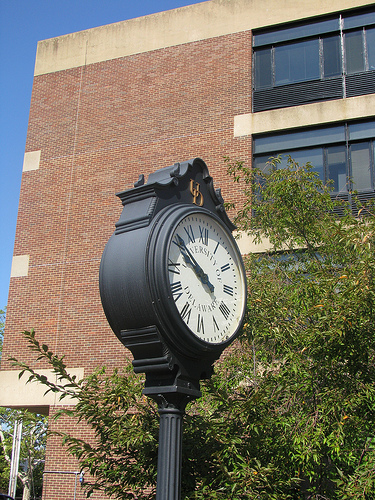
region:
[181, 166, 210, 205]
UD on the clock.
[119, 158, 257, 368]
The frame is black.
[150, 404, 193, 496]
The pole is black.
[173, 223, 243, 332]
The numbers are Roman Numerals.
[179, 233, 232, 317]
University of Delaware on the clock.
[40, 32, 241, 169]
The building is brick.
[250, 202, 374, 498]
The leaves are green.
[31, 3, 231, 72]
Tan on the building.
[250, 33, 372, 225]
Windows on the building.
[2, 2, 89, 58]
The sky is white.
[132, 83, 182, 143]
4 story red brick building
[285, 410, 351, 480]
leafy tree with small leaves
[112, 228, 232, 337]
black and white clock on pole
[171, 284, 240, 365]
face of clock has roman numerals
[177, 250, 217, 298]
black hands on clock face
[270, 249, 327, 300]
windows partially hidden by tree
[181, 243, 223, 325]
black words on white face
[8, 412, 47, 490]
tree near brick building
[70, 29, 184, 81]
tan border at top of roof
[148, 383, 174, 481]
pole is black and ornate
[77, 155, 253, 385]
a clock on a pole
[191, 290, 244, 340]
clock numbers on a clock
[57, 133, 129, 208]
bricks on a building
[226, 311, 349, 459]
tree beside the clock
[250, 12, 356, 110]
window in a building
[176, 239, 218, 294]
hands on a clock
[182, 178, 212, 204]
letters on a clock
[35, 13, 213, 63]
concert edge of roof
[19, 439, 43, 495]
a tree behind the building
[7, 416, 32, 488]
a metal pole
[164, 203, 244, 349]
clock with roman numerals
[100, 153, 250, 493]
fancy black clock on street pole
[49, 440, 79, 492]
exterior brick wall on a building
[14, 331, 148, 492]
green tree branches sticking out of a tree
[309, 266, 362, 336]
orange and green leaves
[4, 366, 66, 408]
large beige brick on wall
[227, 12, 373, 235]
large dark windows on a building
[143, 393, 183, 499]
steel pole holding clock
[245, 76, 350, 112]
black vent on a window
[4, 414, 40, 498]
light wood tree branches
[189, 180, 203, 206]
Golden U and D letters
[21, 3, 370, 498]
big brick building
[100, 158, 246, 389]
a black metal clock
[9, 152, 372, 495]
a green tree behind the clock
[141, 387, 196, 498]
a pole with a clock on it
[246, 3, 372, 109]
big windows on the front of the building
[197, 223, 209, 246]
the 12th hour mark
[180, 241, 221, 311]
"university of Delaware" written on the clock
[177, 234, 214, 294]
hands of the clock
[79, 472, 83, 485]
blue light on the building